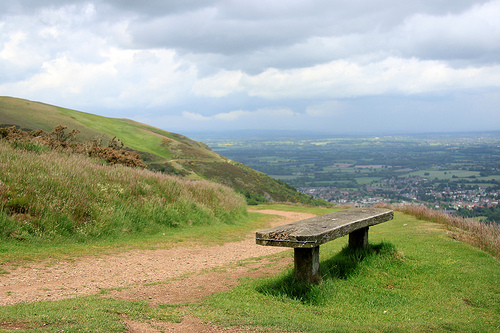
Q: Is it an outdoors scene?
A: Yes, it is outdoors.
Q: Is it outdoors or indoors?
A: It is outdoors.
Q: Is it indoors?
A: No, it is outdoors.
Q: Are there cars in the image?
A: No, there are no cars.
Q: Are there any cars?
A: No, there are no cars.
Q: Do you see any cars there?
A: No, there are no cars.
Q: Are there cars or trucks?
A: No, there are no cars or trucks.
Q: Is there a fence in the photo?
A: No, there are no fences.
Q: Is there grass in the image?
A: Yes, there is grass.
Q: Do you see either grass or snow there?
A: Yes, there is grass.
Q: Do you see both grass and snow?
A: No, there is grass but no snow.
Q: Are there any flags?
A: No, there are no flags.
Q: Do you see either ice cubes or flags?
A: No, there are no flags or ice cubes.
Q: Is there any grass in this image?
A: Yes, there is grass.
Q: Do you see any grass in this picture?
A: Yes, there is grass.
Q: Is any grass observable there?
A: Yes, there is grass.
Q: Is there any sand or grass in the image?
A: Yes, there is grass.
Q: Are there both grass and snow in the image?
A: No, there is grass but no snow.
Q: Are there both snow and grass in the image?
A: No, there is grass but no snow.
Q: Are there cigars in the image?
A: No, there are no cigars.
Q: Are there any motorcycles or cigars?
A: No, there are no cigars or motorcycles.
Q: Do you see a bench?
A: Yes, there is a bench.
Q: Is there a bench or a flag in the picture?
A: Yes, there is a bench.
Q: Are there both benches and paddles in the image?
A: No, there is a bench but no paddles.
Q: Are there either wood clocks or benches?
A: Yes, there is a wood bench.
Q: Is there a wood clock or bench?
A: Yes, there is a wood bench.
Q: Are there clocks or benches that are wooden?
A: Yes, the bench is wooden.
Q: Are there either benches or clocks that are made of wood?
A: Yes, the bench is made of wood.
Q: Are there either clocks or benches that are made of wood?
A: Yes, the bench is made of wood.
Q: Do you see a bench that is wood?
A: Yes, there is a wood bench.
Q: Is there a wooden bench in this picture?
A: Yes, there is a wood bench.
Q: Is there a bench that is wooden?
A: Yes, there is a bench that is wooden.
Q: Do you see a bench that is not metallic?
A: Yes, there is a wooden bench.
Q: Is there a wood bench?
A: Yes, there is a bench that is made of wood.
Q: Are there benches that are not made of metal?
A: Yes, there is a bench that is made of wood.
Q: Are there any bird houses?
A: No, there are no bird houses.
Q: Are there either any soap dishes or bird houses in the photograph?
A: No, there are no bird houses or soap dishes.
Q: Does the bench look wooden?
A: Yes, the bench is wooden.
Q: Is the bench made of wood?
A: Yes, the bench is made of wood.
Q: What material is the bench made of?
A: The bench is made of wood.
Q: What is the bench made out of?
A: The bench is made of wood.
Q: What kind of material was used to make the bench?
A: The bench is made of wood.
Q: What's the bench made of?
A: The bench is made of wood.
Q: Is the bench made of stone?
A: No, the bench is made of wood.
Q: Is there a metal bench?
A: No, there is a bench but it is made of wood.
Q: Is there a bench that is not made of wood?
A: No, there is a bench but it is made of wood.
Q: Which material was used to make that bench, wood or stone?
A: The bench is made of wood.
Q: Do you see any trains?
A: No, there are no trains.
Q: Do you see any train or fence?
A: No, there are no trains or fences.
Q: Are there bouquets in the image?
A: No, there are no bouquets.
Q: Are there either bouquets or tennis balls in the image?
A: No, there are no bouquets or tennis balls.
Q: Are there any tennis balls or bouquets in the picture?
A: No, there are no bouquets or tennis balls.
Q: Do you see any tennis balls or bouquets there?
A: No, there are no bouquets or tennis balls.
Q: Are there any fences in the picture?
A: No, there are no fences.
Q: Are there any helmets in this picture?
A: No, there are no helmets.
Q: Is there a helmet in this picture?
A: No, there are no helmets.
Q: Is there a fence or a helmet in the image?
A: No, there are no helmets or fences.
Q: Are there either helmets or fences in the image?
A: No, there are no helmets or fences.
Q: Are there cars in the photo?
A: No, there are no cars.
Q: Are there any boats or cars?
A: No, there are no cars or boats.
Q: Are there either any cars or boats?
A: No, there are no cars or boats.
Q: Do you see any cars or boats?
A: No, there are no cars or boats.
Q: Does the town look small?
A: Yes, the town is small.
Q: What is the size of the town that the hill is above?
A: The town is small.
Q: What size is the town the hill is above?
A: The town is small.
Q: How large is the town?
A: The town is small.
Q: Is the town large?
A: No, the town is small.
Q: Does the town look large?
A: No, the town is small.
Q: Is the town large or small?
A: The town is small.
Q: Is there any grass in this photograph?
A: Yes, there is grass.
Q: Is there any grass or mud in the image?
A: Yes, there is grass.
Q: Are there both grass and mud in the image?
A: No, there is grass but no mud.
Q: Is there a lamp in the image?
A: No, there are no lamps.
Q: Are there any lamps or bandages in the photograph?
A: No, there are no lamps or bandages.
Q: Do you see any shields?
A: No, there are no shields.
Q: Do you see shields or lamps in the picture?
A: No, there are no shields or lamps.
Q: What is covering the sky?
A: The clouds are covering the sky.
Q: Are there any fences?
A: No, there are no fences.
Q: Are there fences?
A: No, there are no fences.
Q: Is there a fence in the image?
A: No, there are no fences.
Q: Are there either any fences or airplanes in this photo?
A: No, there are no fences or airplanes.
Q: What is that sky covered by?
A: The sky is covered by the clouds.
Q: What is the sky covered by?
A: The sky is covered by the clouds.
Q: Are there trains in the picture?
A: No, there are no trains.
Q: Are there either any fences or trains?
A: No, there are no trains or fences.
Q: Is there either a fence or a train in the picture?
A: No, there are no trains or fences.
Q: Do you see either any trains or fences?
A: No, there are no trains or fences.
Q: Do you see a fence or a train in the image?
A: No, there are no trains or fences.